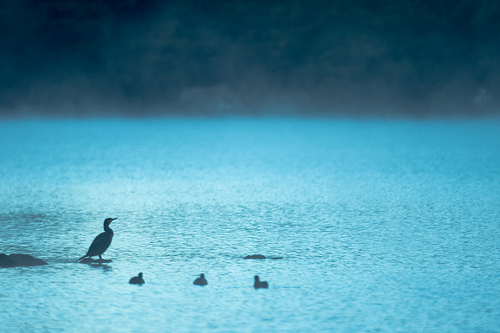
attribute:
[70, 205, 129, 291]
duck — silhouetted, baby, looking over water, large, adult, grown, standing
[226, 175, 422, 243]
water — blue, clear, rippled, teal, bright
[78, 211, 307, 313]
ducks — swimming, pictured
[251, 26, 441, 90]
trees — green, brown, in background